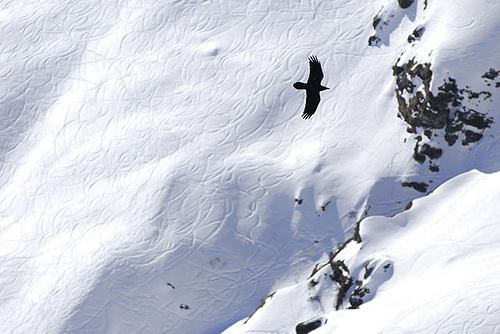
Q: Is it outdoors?
A: Yes, it is outdoors.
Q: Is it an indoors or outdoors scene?
A: It is outdoors.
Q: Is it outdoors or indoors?
A: It is outdoors.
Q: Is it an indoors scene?
A: No, it is outdoors.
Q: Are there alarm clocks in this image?
A: No, there are no alarm clocks.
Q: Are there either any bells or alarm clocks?
A: No, there are no alarm clocks or bells.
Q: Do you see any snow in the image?
A: Yes, there is snow.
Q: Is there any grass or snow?
A: Yes, there is snow.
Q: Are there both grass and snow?
A: No, there is snow but no grass.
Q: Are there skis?
A: No, there are no skis.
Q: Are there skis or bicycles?
A: No, there are no skis or bicycles.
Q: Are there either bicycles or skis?
A: No, there are no skis or bicycles.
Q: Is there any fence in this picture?
A: No, there are no fences.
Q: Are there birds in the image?
A: Yes, there is a bird.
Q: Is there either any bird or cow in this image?
A: Yes, there is a bird.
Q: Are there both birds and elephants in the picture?
A: No, there is a bird but no elephants.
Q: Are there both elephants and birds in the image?
A: No, there is a bird but no elephants.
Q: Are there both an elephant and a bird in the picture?
A: No, there is a bird but no elephants.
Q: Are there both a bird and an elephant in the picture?
A: No, there is a bird but no elephants.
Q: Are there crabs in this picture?
A: No, there are no crabs.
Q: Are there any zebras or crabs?
A: No, there are no crabs or zebras.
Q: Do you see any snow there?
A: Yes, there is snow.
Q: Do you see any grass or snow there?
A: Yes, there is snow.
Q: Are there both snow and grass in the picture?
A: No, there is snow but no grass.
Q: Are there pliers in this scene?
A: No, there are no pliers.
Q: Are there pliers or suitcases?
A: No, there are no pliers or suitcases.